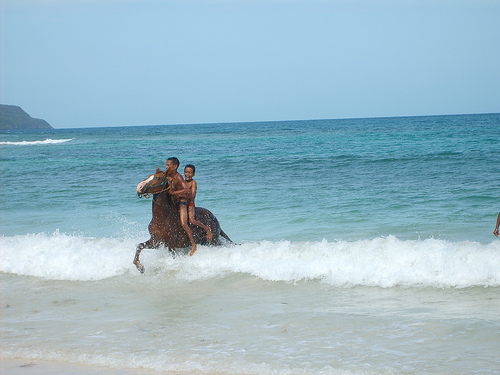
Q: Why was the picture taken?
A: To show the horse riders.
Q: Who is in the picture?
A: 2 people on horses.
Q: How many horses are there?
A: 1.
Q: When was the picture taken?
A: In the daytime.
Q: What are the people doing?
A: Riding a horse.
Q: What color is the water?
A: Blue.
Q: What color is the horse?
A: Brown.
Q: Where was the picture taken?
A: On a beach.